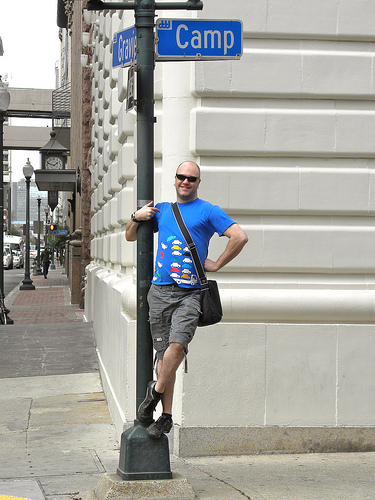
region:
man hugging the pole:
[106, 122, 260, 407]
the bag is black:
[185, 261, 251, 340]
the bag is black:
[166, 251, 231, 345]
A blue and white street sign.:
[105, 18, 243, 61]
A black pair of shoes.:
[139, 384, 176, 439]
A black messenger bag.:
[170, 199, 224, 322]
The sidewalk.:
[3, 234, 372, 498]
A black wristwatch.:
[130, 211, 141, 224]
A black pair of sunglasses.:
[174, 170, 200, 182]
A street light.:
[21, 155, 38, 290]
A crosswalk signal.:
[45, 221, 55, 229]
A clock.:
[42, 152, 67, 172]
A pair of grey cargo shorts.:
[150, 285, 203, 358]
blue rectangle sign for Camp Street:
[155, 15, 243, 57]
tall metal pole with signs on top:
[87, 0, 243, 480]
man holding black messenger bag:
[171, 201, 221, 327]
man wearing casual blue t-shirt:
[148, 197, 236, 289]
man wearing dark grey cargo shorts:
[147, 281, 203, 373]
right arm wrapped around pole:
[125, 201, 161, 241]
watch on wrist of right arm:
[130, 212, 141, 221]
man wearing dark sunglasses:
[174, 172, 199, 181]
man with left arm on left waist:
[204, 199, 250, 271]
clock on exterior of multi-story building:
[45, 154, 63, 168]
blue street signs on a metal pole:
[111, 18, 246, 61]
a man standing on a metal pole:
[125, 161, 247, 436]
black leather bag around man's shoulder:
[169, 201, 223, 326]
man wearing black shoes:
[135, 381, 175, 439]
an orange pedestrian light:
[47, 223, 57, 229]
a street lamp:
[20, 155, 35, 290]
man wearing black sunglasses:
[175, 170, 199, 182]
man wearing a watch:
[130, 210, 142, 227]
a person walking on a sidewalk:
[38, 243, 53, 279]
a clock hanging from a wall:
[38, 129, 70, 170]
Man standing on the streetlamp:
[121, 157, 251, 442]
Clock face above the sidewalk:
[39, 154, 69, 173]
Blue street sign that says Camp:
[153, 13, 247, 63]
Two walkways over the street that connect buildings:
[0, 78, 77, 157]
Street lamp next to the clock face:
[14, 153, 37, 293]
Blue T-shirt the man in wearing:
[153, 198, 236, 289]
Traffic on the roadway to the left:
[2, 225, 32, 282]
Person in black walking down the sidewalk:
[37, 245, 56, 281]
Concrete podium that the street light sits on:
[89, 469, 201, 499]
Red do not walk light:
[45, 222, 58, 234]